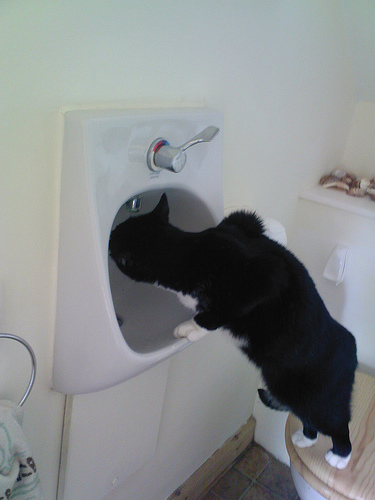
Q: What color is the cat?
A: Black.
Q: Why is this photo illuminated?
A: Light fixture.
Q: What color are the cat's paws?
A: White.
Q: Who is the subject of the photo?
A: The cat.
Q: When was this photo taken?
A: During the day.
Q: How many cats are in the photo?
A: One.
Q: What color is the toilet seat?
A: Brown.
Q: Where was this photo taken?
A: In a bathroom.